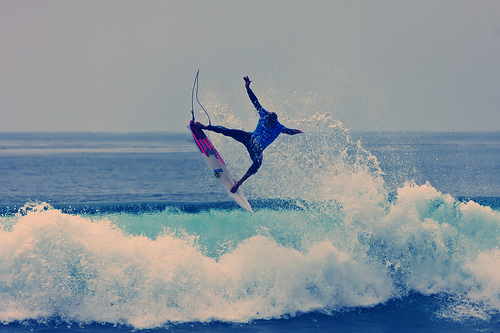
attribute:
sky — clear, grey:
[3, 4, 494, 134]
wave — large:
[2, 173, 496, 319]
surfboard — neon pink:
[178, 115, 273, 219]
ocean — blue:
[1, 131, 498, 331]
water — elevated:
[164, 140, 494, 321]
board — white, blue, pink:
[188, 110, 255, 220]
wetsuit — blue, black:
[193, 85, 293, 195]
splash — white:
[136, 236, 211, 294]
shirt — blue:
[250, 105, 294, 155]